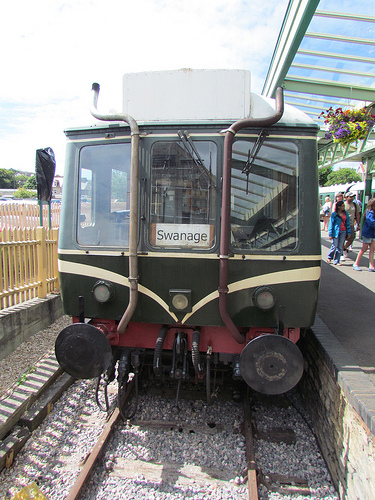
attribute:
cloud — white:
[2, 1, 290, 175]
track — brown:
[65, 381, 137, 499]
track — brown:
[239, 395, 259, 499]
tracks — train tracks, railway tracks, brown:
[63, 376, 262, 499]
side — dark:
[75, 412, 124, 500]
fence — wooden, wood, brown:
[1, 225, 62, 309]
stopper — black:
[238, 334, 305, 395]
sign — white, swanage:
[154, 221, 211, 250]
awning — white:
[258, 1, 374, 96]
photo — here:
[0, 1, 373, 500]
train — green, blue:
[55, 70, 321, 417]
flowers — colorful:
[319, 100, 373, 149]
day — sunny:
[0, 1, 373, 499]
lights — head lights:
[93, 282, 276, 311]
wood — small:
[207, 420, 218, 428]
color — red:
[93, 317, 300, 353]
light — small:
[254, 289, 275, 312]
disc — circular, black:
[55, 322, 110, 380]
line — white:
[222, 253, 319, 261]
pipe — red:
[359, 160, 367, 176]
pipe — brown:
[89, 82, 142, 333]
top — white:
[63, 68, 322, 130]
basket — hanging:
[329, 110, 358, 146]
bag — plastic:
[37, 147, 56, 205]